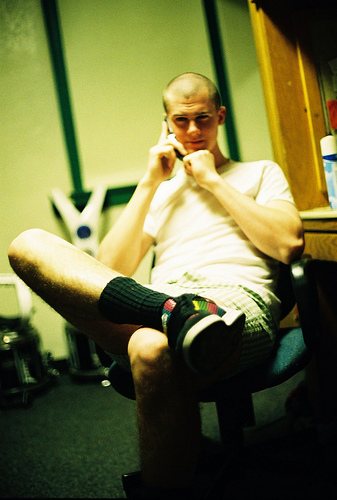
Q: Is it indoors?
A: Yes, it is indoors.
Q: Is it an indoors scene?
A: Yes, it is indoors.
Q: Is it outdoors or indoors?
A: It is indoors.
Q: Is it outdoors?
A: No, it is indoors.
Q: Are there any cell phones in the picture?
A: Yes, there is a cell phone.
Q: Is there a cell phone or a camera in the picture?
A: Yes, there is a cell phone.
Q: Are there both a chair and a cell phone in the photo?
A: Yes, there are both a cell phone and a chair.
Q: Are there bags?
A: No, there are no bags.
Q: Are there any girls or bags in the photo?
A: No, there are no bags or girls.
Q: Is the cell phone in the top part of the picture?
A: Yes, the cell phone is in the top of the image.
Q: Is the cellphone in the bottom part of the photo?
A: No, the cellphone is in the top of the image.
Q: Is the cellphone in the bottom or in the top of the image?
A: The cellphone is in the top of the image.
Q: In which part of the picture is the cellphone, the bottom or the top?
A: The cellphone is in the top of the image.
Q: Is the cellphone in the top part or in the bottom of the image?
A: The cellphone is in the top of the image.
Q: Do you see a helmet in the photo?
A: No, there are no helmets.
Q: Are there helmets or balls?
A: No, there are no helmets or balls.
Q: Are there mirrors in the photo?
A: No, there are no mirrors.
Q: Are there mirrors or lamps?
A: No, there are no mirrors or lamps.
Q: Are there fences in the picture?
A: No, there are no fences.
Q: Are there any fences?
A: No, there are no fences.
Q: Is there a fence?
A: No, there are no fences.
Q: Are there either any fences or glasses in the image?
A: No, there are no fences or glasses.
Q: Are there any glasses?
A: No, there are no glasses.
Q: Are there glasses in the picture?
A: No, there are no glasses.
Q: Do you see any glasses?
A: No, there are no glasses.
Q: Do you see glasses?
A: No, there are no glasses.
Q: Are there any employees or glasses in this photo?
A: No, there are no glasses or employees.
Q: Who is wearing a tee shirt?
A: The man is wearing a tee shirt.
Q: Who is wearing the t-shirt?
A: The man is wearing a tee shirt.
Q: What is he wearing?
A: The man is wearing a t-shirt.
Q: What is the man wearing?
A: The man is wearing a t-shirt.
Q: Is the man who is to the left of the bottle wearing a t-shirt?
A: Yes, the man is wearing a t-shirt.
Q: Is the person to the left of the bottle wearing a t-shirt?
A: Yes, the man is wearing a t-shirt.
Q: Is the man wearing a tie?
A: No, the man is wearing a t-shirt.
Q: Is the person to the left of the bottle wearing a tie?
A: No, the man is wearing a t-shirt.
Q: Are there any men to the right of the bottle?
A: No, the man is to the left of the bottle.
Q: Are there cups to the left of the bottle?
A: No, there is a man to the left of the bottle.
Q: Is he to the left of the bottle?
A: Yes, the man is to the left of the bottle.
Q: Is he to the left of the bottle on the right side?
A: Yes, the man is to the left of the bottle.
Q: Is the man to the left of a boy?
A: No, the man is to the left of the bottle.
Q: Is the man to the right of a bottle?
A: No, the man is to the left of a bottle.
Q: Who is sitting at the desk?
A: The man is sitting at the desk.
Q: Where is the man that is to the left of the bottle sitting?
A: The man is sitting at the desk.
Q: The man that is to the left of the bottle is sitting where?
A: The man is sitting at the desk.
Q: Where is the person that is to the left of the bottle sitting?
A: The man is sitting at the desk.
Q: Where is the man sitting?
A: The man is sitting at the desk.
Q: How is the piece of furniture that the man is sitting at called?
A: The piece of furniture is a desk.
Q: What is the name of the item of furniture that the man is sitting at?
A: The piece of furniture is a desk.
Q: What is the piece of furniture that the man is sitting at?
A: The piece of furniture is a desk.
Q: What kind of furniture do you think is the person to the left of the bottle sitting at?
A: The man is sitting at the desk.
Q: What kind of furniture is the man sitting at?
A: The man is sitting at the desk.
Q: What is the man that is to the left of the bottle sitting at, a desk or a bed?
A: The man is sitting at a desk.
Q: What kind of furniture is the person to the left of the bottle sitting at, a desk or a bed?
A: The man is sitting at a desk.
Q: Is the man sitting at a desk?
A: Yes, the man is sitting at a desk.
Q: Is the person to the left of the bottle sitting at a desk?
A: Yes, the man is sitting at a desk.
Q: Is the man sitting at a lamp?
A: No, the man is sitting at a desk.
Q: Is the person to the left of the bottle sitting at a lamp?
A: No, the man is sitting at a desk.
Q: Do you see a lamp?
A: No, there are no lamps.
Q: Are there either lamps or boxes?
A: No, there are no lamps or boxes.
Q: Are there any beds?
A: No, there are no beds.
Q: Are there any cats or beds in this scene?
A: No, there are no beds or cats.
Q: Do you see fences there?
A: No, there are no fences.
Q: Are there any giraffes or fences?
A: No, there are no fences or giraffes.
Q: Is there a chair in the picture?
A: Yes, there is a chair.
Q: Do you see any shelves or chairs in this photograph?
A: Yes, there is a chair.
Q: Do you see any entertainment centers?
A: No, there are no entertainment centers.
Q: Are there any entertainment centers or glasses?
A: No, there are no entertainment centers or glasses.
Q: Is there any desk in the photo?
A: Yes, there is a desk.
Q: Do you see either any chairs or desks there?
A: Yes, there is a desk.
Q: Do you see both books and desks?
A: No, there is a desk but no books.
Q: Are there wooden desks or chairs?
A: Yes, there is a wood desk.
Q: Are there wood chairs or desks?
A: Yes, there is a wood desk.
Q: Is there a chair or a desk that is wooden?
A: Yes, the desk is wooden.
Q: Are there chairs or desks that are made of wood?
A: Yes, the desk is made of wood.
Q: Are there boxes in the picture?
A: No, there are no boxes.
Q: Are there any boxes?
A: No, there are no boxes.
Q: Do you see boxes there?
A: No, there are no boxes.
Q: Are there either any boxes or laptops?
A: No, there are no boxes or laptops.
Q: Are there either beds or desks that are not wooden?
A: No, there is a desk but it is wooden.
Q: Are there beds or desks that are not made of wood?
A: No, there is a desk but it is made of wood.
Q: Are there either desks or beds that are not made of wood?
A: No, there is a desk but it is made of wood.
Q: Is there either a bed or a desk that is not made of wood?
A: No, there is a desk but it is made of wood.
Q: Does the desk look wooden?
A: Yes, the desk is wooden.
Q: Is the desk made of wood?
A: Yes, the desk is made of wood.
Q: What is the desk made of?
A: The desk is made of wood.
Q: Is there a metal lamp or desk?
A: No, there is a desk but it is wooden.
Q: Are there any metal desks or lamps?
A: No, there is a desk but it is wooden.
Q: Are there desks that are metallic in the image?
A: No, there is a desk but it is wooden.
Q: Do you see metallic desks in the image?
A: No, there is a desk but it is wooden.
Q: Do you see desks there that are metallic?
A: No, there is a desk but it is wooden.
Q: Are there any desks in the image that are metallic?
A: No, there is a desk but it is wooden.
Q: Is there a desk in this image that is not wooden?
A: No, there is a desk but it is wooden.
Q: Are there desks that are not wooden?
A: No, there is a desk but it is wooden.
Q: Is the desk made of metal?
A: No, the desk is made of wood.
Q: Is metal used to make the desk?
A: No, the desk is made of wood.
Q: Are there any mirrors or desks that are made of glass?
A: No, there is a desk but it is made of wood.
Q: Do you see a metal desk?
A: No, there is a desk but it is made of wood.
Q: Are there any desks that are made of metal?
A: No, there is a desk but it is made of wood.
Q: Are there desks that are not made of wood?
A: No, there is a desk but it is made of wood.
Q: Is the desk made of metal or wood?
A: The desk is made of wood.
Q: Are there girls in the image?
A: No, there are no girls.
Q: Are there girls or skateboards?
A: No, there are no girls or skateboards.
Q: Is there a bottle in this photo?
A: Yes, there is a bottle.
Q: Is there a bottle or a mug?
A: Yes, there is a bottle.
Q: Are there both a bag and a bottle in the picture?
A: No, there is a bottle but no bags.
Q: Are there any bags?
A: No, there are no bags.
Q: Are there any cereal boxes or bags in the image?
A: No, there are no bags or cereal boxes.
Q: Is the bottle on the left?
A: No, the bottle is on the right of the image.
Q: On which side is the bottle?
A: The bottle is on the right of the image.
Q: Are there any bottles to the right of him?
A: Yes, there is a bottle to the right of the man.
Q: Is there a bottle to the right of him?
A: Yes, there is a bottle to the right of the man.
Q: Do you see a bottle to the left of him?
A: No, the bottle is to the right of the man.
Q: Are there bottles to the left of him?
A: No, the bottle is to the right of the man.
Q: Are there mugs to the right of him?
A: No, there is a bottle to the right of the man.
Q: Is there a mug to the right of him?
A: No, there is a bottle to the right of the man.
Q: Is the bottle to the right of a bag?
A: No, the bottle is to the right of the man.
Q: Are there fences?
A: No, there are no fences.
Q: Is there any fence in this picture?
A: No, there are no fences.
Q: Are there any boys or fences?
A: No, there are no fences or boys.